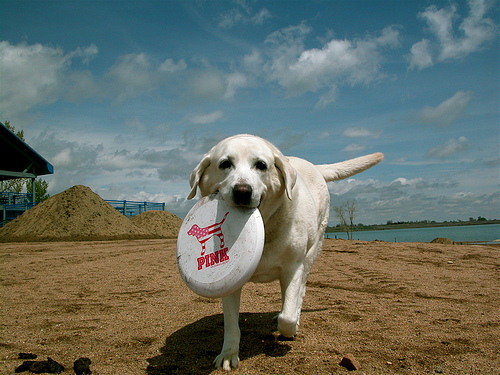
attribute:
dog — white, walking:
[186, 133, 384, 372]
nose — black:
[232, 182, 253, 199]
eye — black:
[218, 157, 232, 171]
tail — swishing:
[312, 152, 384, 181]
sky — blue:
[0, 0, 499, 226]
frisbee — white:
[175, 194, 265, 300]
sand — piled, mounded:
[1, 185, 156, 240]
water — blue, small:
[323, 223, 499, 245]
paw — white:
[212, 352, 243, 372]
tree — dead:
[332, 197, 360, 241]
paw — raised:
[276, 313, 298, 338]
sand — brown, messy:
[1, 239, 499, 372]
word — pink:
[196, 246, 229, 270]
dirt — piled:
[128, 210, 184, 239]